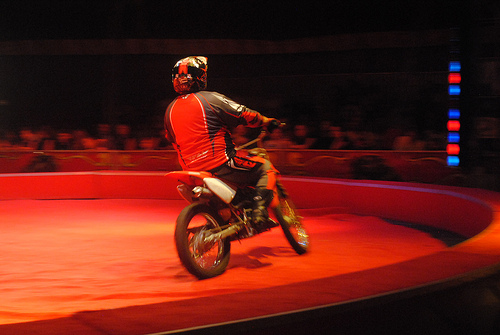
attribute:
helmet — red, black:
[172, 52, 209, 96]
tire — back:
[160, 194, 250, 279]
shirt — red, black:
[152, 94, 266, 176]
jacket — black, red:
[166, 87, 259, 179]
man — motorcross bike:
[162, 51, 275, 220]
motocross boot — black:
[246, 188, 272, 219]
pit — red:
[55, 210, 113, 267]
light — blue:
[441, 60, 462, 72]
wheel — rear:
[137, 162, 270, 297]